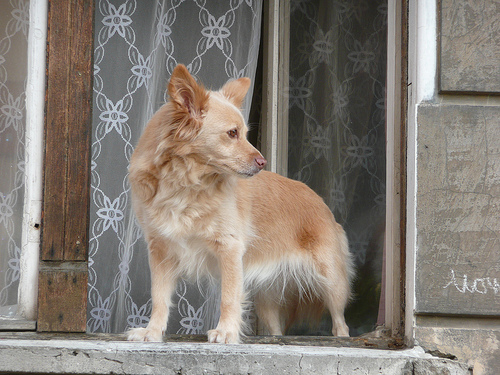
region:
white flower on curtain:
[100, 99, 141, 133]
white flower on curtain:
[130, 55, 155, 90]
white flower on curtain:
[198, 12, 232, 53]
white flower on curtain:
[106, 10, 141, 46]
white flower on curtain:
[103, 194, 129, 231]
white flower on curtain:
[112, 249, 134, 289]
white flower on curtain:
[87, 297, 112, 329]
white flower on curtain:
[124, 297, 155, 337]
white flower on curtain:
[184, 305, 215, 342]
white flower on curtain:
[241, 301, 262, 335]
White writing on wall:
[447, 268, 499, 298]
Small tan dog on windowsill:
[130, 64, 352, 353]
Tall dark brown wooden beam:
[37, 0, 94, 337]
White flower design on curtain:
[199, 14, 231, 49]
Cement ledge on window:
[3, 342, 425, 374]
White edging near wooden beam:
[20, 0, 46, 320]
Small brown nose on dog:
[256, 154, 266, 167]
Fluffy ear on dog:
[167, 63, 207, 112]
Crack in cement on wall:
[418, 342, 468, 367]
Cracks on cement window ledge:
[53, 347, 322, 372]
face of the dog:
[174, 62, 285, 190]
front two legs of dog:
[124, 278, 275, 340]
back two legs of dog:
[261, 291, 377, 343]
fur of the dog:
[247, 212, 298, 264]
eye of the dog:
[218, 112, 246, 152]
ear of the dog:
[145, 65, 212, 120]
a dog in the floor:
[118, 46, 380, 356]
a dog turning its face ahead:
[110, 37, 390, 354]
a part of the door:
[384, 12, 459, 360]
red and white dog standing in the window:
[124, 62, 356, 346]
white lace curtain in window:
[2, 0, 389, 336]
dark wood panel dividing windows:
[33, 0, 97, 332]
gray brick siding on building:
[413, 1, 498, 371]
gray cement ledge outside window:
[0, 338, 475, 374]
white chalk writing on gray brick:
[440, 268, 497, 295]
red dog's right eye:
[223, 127, 239, 139]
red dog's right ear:
[166, 62, 204, 115]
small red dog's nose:
[251, 155, 266, 167]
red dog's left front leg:
[204, 242, 246, 346]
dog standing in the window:
[106, 66, 367, 353]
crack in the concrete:
[294, 351, 307, 371]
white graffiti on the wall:
[441, 260, 499, 301]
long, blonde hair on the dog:
[117, 65, 370, 335]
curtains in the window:
[93, 3, 263, 335]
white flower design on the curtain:
[98, 97, 130, 135]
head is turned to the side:
[160, 56, 275, 182]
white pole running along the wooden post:
[17, 3, 56, 328]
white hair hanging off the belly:
[243, 258, 330, 300]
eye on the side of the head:
[221, 128, 240, 141]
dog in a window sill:
[105, 60, 366, 347]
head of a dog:
[160, 63, 270, 184]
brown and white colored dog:
[114, 62, 371, 349]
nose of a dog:
[253, 152, 267, 172]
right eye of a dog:
[220, 123, 240, 144]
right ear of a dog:
[166, 61, 210, 119]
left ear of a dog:
[220, 70, 253, 109]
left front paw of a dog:
[204, 325, 239, 346]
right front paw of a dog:
[118, 323, 175, 348]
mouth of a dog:
[222, 161, 252, 178]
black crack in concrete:
[332, 357, 344, 374]